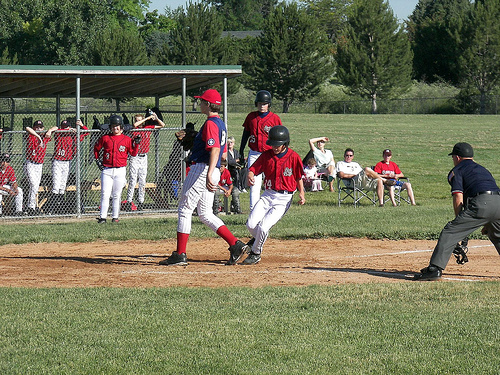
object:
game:
[0, 84, 500, 282]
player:
[240, 123, 308, 265]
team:
[0, 89, 288, 224]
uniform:
[429, 158, 500, 271]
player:
[237, 89, 283, 216]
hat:
[192, 88, 223, 106]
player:
[412, 140, 500, 282]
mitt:
[452, 234, 471, 266]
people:
[335, 146, 398, 208]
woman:
[308, 135, 338, 193]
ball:
[245, 245, 253, 255]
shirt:
[449, 158, 500, 204]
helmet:
[265, 124, 292, 149]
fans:
[93, 115, 143, 225]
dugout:
[0, 61, 242, 224]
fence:
[0, 127, 228, 220]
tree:
[236, 0, 339, 114]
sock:
[173, 229, 189, 255]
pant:
[173, 164, 228, 235]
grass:
[0, 112, 500, 205]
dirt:
[289, 240, 388, 276]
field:
[0, 112, 500, 375]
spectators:
[24, 119, 59, 216]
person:
[120, 108, 166, 206]